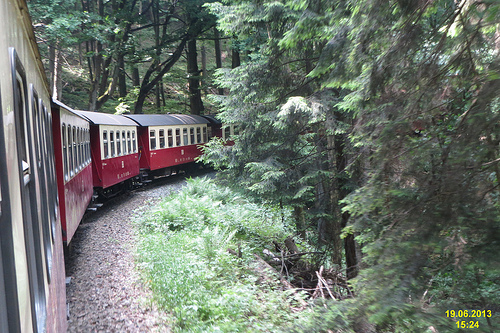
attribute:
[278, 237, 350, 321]
sticks — piled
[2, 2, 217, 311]
train — curved, topped, carred, red, white, roofed, dated, rounding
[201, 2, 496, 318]
trees — evergreen, green, brown, leafy, black, trunked, branched, leaved, forested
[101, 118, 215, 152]
windows — trimmed, white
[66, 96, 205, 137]
roof — grey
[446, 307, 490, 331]
lettering — gold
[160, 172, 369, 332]
grass — high, green, dirty, rocky, present, shining